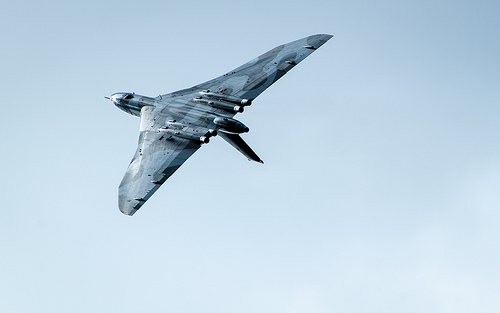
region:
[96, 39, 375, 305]
a jet is flying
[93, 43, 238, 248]
A jet plane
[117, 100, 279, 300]
A jet plane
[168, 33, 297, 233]
A jet plane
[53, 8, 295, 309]
A jet plane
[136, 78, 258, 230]
A jet plane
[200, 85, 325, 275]
A jet plane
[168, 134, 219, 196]
A jet plane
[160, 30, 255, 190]
A jet plane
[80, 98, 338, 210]
A jet plane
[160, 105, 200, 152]
A jet plane is visible.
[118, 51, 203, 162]
A jet plane is visible.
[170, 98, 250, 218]
A jet plane is visible.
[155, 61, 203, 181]
A jet plane is visible.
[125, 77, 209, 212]
A jet plane is visible.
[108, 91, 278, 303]
A jet plane is visible.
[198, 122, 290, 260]
A jet plane is visible.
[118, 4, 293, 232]
A jet plane is visible.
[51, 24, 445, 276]
an airplane flying upside down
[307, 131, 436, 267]
clear blue skies in the background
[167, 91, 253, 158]
the jet planes engines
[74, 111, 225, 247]
the jet planes wings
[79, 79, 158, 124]
the nose of the jet plane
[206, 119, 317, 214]
the tale of the jet plane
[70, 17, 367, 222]
the jet plane is turning on inside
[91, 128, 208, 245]
a camouflage paint job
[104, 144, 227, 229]
the flaps of the jet plane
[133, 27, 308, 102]
the wing edge of the jet plane